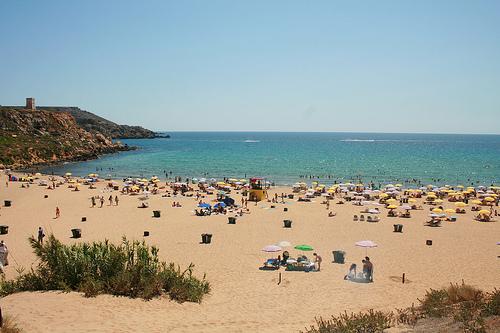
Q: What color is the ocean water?
A: Clear blue.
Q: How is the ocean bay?
A: Calm.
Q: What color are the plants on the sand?
A: Green.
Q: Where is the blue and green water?
A: By a beach.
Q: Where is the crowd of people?
A: On a beach.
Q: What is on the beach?
A: A crowd of people.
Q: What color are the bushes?
A: Green and brown.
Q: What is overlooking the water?
A: Mountain.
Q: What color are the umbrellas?
A: Yellow.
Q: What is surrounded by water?
A: The landscape.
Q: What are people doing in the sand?
A: Playing.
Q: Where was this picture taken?
A: A beach.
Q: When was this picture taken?
A: Summer.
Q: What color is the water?
A: Blue.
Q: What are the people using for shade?
A: Umbrellas.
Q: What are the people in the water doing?
A: Swimming.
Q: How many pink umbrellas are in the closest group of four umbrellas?
A: Three.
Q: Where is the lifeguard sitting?
A: On the yellow tower.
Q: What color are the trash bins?
A: Black.